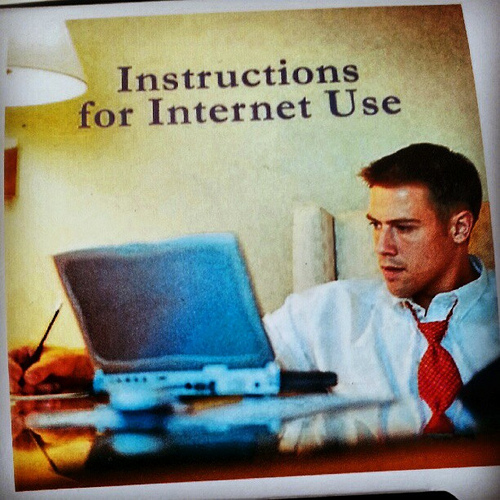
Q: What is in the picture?
A: Guy.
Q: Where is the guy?
A: Behind the desk.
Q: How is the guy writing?
A: With a pen.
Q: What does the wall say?
A: Instructions for Internet Use.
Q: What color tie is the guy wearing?
A: Red.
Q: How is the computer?
A: Opened.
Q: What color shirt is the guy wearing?
A: White.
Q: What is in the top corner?
A: Lamp.